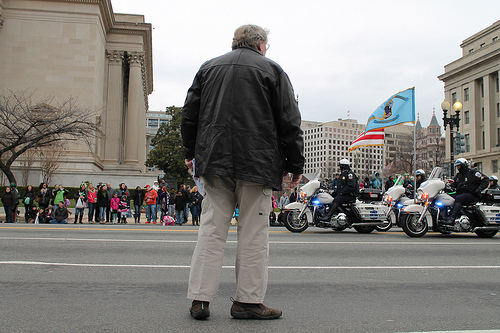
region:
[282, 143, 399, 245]
The man is riding a motorcycle.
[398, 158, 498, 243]
The man is riding a motorcycle.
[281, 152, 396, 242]
The man is wearing a helmet.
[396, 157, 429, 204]
The man is wearing a helmet.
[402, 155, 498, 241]
The man is wearing a helmet.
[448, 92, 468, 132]
The streetlamp is on.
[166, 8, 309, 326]
The man is standing.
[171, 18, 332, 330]
The man is in the street.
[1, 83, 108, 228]
The tree is bare.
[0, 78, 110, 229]
The tree is leafless.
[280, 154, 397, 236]
a cop riding a motorcycle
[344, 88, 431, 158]
some flags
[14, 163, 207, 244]
a crowd of people watching a parade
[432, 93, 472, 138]
some ornamental light fixtures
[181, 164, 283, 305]
tan pants worn by a man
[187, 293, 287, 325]
brown shoes worn by a man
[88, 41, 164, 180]
columns on the exterior of a building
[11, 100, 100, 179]
a tree without leaves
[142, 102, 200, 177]
a tree with green leaves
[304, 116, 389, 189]
a large office building with many windows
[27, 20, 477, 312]
picture taken on a city street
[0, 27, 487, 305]
picture taken at a parade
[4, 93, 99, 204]
tree with no leaves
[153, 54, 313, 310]
man wearing a black leather jacket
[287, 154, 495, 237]
three police motorcycles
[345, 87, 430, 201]
flags attached to police motorcycles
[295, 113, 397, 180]
white building with many windows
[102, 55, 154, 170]
tan columns on building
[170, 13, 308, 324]
man standing on street wearing khakis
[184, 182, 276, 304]
man wearing khaki pants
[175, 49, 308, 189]
man wearing black jacket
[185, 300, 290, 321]
man wearing brown moccasin shoes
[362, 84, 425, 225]
blue flag flying on street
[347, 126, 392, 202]
American flag flying on street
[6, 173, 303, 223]
spectators lining street to watch parade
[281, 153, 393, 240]
policeman riding on motorcycle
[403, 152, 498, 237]
policeman riding on motorcycle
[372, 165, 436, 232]
policeman riding on motorcycle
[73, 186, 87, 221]
person in the crowd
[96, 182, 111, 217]
person in the crowd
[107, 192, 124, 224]
person in the crowd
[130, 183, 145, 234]
person in the crowd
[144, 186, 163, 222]
person in the crowd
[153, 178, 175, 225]
person in the crowd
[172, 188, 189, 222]
person in the crowd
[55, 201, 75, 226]
person in the crowd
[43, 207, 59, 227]
person in the crowd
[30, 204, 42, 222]
person in the crowd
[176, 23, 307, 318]
back of standing man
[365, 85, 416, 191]
blue flag with emblem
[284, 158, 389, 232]
police officer on motorcycle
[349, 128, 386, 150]
flag with red stripes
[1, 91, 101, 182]
tree with no leaves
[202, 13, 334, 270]
Man standing in the street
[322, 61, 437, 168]
Two flags flying high in the sky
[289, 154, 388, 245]
A police officer on a motorcycle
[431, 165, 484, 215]
A police officer and a blackjack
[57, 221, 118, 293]
White and yellow lines painted on the road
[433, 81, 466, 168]
Streetlight that only one light is lit up